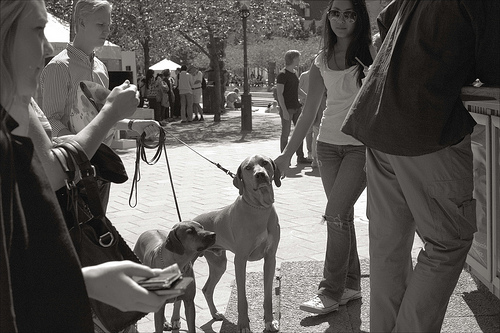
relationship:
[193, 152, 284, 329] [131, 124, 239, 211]
dog on leash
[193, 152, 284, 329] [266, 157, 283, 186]
dog has ear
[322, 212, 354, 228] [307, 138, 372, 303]
tear in jeans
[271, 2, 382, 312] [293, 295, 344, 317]
woman has shoe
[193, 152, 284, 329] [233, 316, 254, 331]
dog has paw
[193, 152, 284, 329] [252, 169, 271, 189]
dog has nose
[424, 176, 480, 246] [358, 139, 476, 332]
pocket on jeans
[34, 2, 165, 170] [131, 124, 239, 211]
man holding leash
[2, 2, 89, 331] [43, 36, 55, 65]
lady has nose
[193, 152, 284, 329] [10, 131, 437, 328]
dog standing on street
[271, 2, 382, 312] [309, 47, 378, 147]
woman wearing shirt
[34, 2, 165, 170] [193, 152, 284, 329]
man looking at dog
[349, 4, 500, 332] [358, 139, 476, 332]
man has jeans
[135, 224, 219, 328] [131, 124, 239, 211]
dog on leash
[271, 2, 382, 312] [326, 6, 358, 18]
woman wearing sunglasses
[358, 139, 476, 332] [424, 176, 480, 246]
jeans have pocket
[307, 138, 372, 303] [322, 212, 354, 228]
jeans have tear